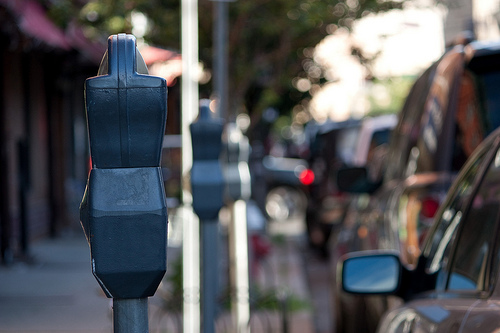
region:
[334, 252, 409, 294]
a side car mirror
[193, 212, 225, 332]
a pole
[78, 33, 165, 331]
a black parking car meter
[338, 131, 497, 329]
a parked car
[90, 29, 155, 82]
the top of a parking meter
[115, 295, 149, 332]
the pole of a parking meter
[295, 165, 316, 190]
the red tail light of a car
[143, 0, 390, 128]
a tree with green leafs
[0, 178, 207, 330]
a sidewalk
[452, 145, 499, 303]
a car back window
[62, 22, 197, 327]
a parking meter on the street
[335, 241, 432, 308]
the side mirrors of a car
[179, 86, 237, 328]
parking meters on the street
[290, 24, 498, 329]
cars parked on the street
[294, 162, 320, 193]
lights coming off from car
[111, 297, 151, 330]
steel poll from the parking meter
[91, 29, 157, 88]
parking meter display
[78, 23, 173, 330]
an old styled parking meter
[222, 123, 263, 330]
parking meter on a street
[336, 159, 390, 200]
side mirrors of a car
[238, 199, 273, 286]
red fire hydrant with white cap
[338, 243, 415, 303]
side view mirror on side of car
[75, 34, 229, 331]
parking meters along the road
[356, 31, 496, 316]
rear of a parked SUV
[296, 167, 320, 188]
a lit rear light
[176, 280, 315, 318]
grass growing up between the sidewalk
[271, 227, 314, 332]
a curb along the street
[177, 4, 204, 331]
a white pole on the sidewalk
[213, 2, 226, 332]
a grey pole on the sidewalk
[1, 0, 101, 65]
red roof on a building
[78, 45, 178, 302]
a parking meter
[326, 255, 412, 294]
a mirror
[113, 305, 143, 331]
a metal pole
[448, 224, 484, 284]
window on the car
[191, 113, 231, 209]
a grey parking meter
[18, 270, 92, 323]
the sidewalk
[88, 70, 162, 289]
the meter is grey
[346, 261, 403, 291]
glass in the mirror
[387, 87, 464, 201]
a car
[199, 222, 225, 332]
a pole on the meter